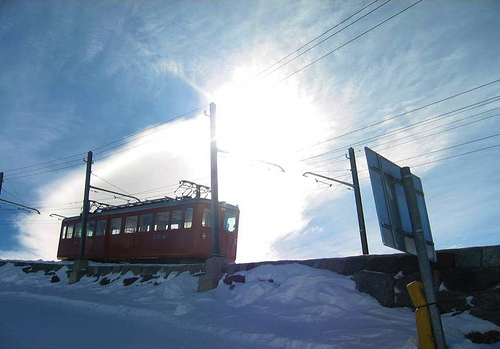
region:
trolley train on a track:
[36, 181, 253, 278]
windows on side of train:
[145, 207, 207, 235]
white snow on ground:
[236, 299, 323, 346]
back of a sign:
[354, 144, 439, 261]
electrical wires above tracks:
[426, 88, 482, 179]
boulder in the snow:
[347, 256, 399, 305]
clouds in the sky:
[12, 64, 149, 124]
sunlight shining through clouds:
[238, 86, 299, 156]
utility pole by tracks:
[76, 144, 102, 295]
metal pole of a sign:
[398, 162, 450, 329]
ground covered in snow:
[20, 297, 360, 347]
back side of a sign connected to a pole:
[360, 145, 442, 260]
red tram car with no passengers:
[47, 175, 253, 272]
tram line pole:
[300, 137, 372, 258]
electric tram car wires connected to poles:
[17, 102, 359, 192]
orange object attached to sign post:
[403, 275, 450, 347]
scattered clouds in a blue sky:
[3, 29, 498, 100]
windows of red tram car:
[87, 211, 192, 233]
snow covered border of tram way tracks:
[2, 257, 363, 273]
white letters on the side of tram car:
[148, 228, 168, 243]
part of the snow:
[296, 295, 314, 307]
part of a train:
[158, 235, 175, 250]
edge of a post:
[282, 313, 302, 337]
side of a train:
[117, 229, 126, 241]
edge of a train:
[191, 204, 206, 249]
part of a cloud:
[270, 219, 285, 238]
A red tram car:
[41, 201, 258, 256]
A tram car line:
[28, 150, 239, 200]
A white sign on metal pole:
[353, 145, 465, 341]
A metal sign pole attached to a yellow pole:
[403, 285, 425, 345]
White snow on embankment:
[245, 267, 351, 327]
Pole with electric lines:
[305, 142, 375, 247]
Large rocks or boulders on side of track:
[350, 261, 420, 306]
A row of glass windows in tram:
[55, 203, 195, 241]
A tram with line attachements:
[80, 177, 211, 209]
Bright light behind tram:
[107, 89, 312, 161]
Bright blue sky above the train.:
[47, 15, 172, 107]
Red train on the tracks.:
[42, 179, 247, 264]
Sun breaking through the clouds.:
[222, 50, 318, 153]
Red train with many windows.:
[55, 200, 200, 242]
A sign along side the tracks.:
[353, 127, 442, 268]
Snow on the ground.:
[45, 298, 217, 338]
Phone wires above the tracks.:
[235, 10, 397, 105]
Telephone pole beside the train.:
[205, 95, 222, 195]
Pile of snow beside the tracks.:
[219, 254, 354, 306]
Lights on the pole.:
[293, 165, 354, 199]